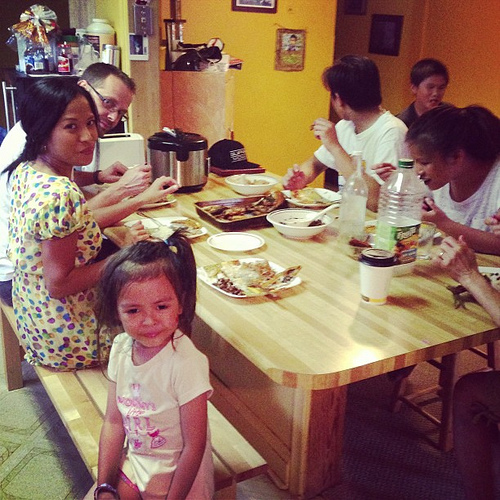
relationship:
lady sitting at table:
[1, 74, 182, 372] [100, 172, 500, 390]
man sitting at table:
[2, 62, 152, 307] [100, 172, 500, 390]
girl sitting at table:
[93, 229, 214, 500] [100, 172, 500, 390]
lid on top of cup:
[360, 249, 397, 268] [358, 264, 396, 306]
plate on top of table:
[207, 232, 266, 251] [100, 172, 500, 390]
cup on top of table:
[358, 264, 396, 306] [100, 172, 500, 390]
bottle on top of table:
[339, 151, 368, 239] [100, 172, 500, 390]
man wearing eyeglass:
[2, 62, 152, 307] [83, 79, 130, 124]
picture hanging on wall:
[274, 27, 306, 72] [159, 0, 499, 187]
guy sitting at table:
[283, 52, 433, 221] [100, 172, 500, 390]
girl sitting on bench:
[93, 229, 214, 500] [0, 297, 270, 499]